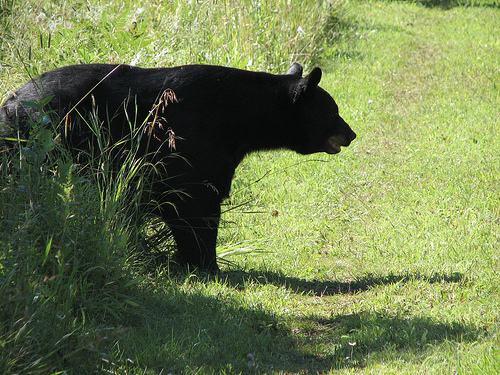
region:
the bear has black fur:
[13, 31, 498, 338]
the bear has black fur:
[58, 50, 385, 230]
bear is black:
[13, 38, 383, 248]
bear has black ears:
[272, 51, 344, 120]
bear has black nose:
[335, 122, 359, 136]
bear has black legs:
[138, 181, 225, 297]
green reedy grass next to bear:
[6, 108, 143, 367]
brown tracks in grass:
[270, 32, 426, 358]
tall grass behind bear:
[44, 1, 355, 66]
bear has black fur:
[21, 63, 273, 255]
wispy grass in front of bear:
[6, 83, 195, 274]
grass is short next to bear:
[387, 69, 495, 363]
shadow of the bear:
[199, 252, 467, 309]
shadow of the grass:
[238, 305, 483, 372]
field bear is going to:
[356, 160, 451, 284]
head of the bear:
[263, 56, 358, 201]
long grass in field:
[2, 229, 172, 338]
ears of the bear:
[272, 57, 334, 87]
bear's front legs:
[158, 190, 238, 285]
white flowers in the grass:
[126, 13, 201, 50]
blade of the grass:
[242, 202, 269, 218]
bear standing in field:
[3, 49, 357, 286]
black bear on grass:
[58, 46, 406, 282]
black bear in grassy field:
[36, 33, 401, 288]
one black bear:
[40, 43, 405, 284]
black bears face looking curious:
[265, 56, 392, 183]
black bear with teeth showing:
[261, 46, 379, 171]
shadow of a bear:
[118, 238, 478, 312]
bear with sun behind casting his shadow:
[14, 12, 479, 303]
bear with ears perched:
[107, 27, 403, 232]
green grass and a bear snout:
[318, 113, 442, 241]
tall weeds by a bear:
[8, 47, 373, 348]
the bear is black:
[12, 26, 393, 281]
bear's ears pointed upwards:
[270, 31, 345, 111]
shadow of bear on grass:
[140, 197, 475, 347]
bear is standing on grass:
[6, 17, 451, 323]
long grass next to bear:
[11, 95, 226, 365]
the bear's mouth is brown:
[311, 110, 366, 175]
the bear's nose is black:
[342, 120, 357, 140]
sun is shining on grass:
[135, 0, 486, 277]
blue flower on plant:
[30, 104, 75, 153]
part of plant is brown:
[133, 74, 203, 159]